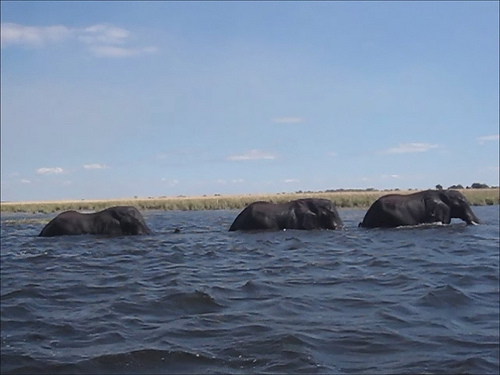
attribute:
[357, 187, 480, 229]
elephant — gray, wet, standing, large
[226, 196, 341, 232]
elephant — gray, wet, standing, large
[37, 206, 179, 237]
elephant — gray, wet, standing, large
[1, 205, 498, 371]
water — blue, choppy, chopp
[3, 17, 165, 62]
clouds — white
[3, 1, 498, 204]
sky — clear, blue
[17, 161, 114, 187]
clouds — white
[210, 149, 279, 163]
clouds — white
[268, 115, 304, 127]
clouds — white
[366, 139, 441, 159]
clouds — white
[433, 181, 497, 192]
trees — green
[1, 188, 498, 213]
land — brown, flat